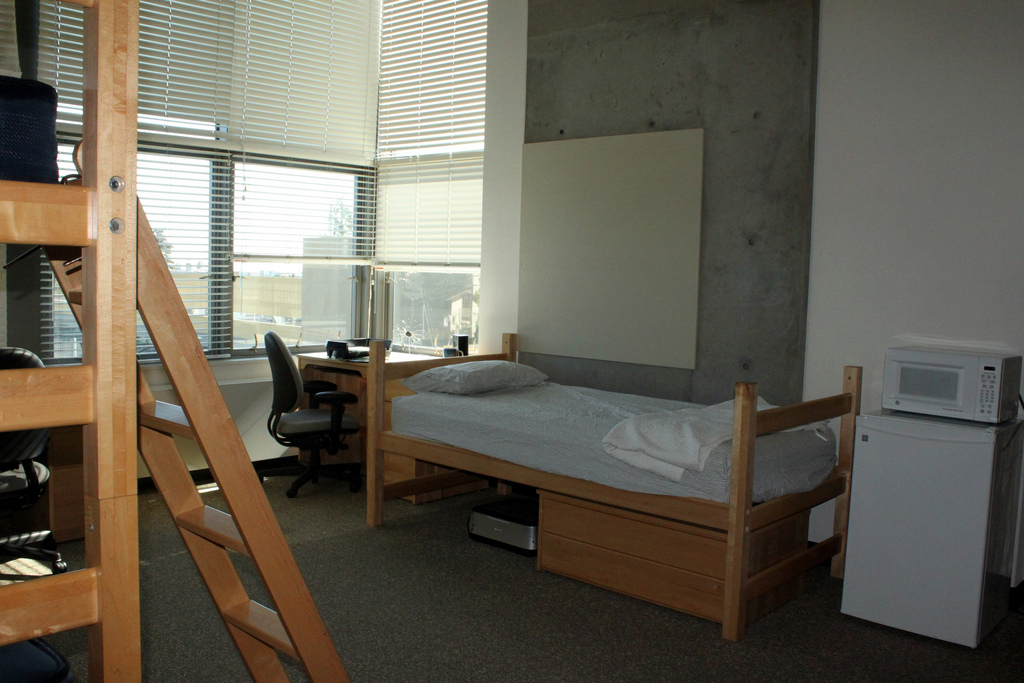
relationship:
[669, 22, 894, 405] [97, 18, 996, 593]
wall of building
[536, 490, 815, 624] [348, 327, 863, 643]
drawer under bed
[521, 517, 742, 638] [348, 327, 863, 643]
drawer under bed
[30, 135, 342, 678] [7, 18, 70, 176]
ladder to bunk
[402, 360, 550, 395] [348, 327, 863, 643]
pillow in bed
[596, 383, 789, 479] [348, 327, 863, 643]
sheet on bed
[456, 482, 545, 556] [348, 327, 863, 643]
object beneath bed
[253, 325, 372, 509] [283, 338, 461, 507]
chair close to desk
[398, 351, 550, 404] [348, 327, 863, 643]
pillow on bed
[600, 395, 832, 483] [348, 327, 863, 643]
sheet on bed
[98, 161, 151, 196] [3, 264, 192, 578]
bolt on bed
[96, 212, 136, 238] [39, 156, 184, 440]
bolt on bed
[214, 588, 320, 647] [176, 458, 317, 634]
wood on ladder